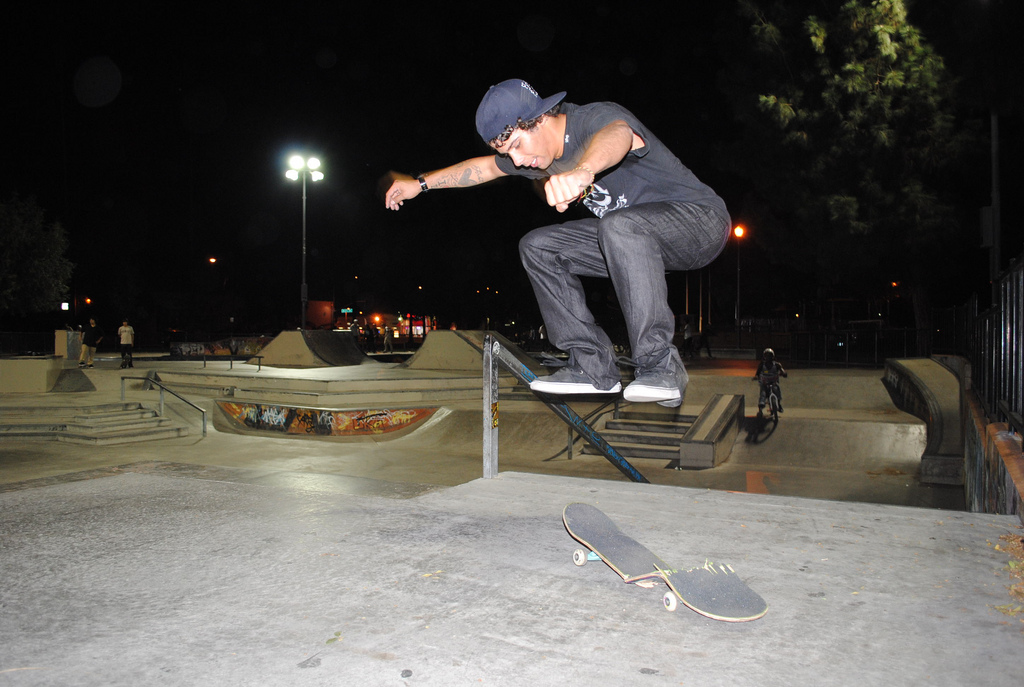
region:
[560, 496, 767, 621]
A broken wooden skateboard.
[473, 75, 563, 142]
A blue cap with white deisgn.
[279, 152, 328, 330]
A lampost with four white lights.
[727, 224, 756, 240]
A round and red light.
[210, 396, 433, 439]
Graffiti on the side of cement.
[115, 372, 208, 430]
A thin and black bar.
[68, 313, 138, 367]
Two guy standing in the background.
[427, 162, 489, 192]
Blank ink on the guys' arm.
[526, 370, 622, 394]
Black shoe with white base.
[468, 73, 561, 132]
Person wearing baseball hat on head.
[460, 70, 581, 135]
Person is wearing blue hat.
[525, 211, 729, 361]
Person wearing dark pants.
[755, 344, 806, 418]
Person in distance is sitting on bike.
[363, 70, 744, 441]
Person is doing a trick over skateboard.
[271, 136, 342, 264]
Large light illuminated in distance.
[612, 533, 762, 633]
Skateboard is broken in pieces.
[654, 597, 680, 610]
wheel attached to skateboard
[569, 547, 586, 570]
wheel attached to skateboard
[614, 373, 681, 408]
shoe on top of foot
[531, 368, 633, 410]
shoe on top of foot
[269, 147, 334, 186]
light fixture attached to pole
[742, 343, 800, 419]
person riding bike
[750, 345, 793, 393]
person on top of bike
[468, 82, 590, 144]
hat on top of head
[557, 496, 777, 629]
skateboard on top of cement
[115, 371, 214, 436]
rail near concrete steps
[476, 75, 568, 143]
Blue hat on a man in the air.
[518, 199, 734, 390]
Black pants on a man in the air.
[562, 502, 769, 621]
Black topped skateboard broken in half.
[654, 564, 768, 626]
Smaller broken half of a skateboard.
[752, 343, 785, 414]
Person on a bicycle at the top of a ramp.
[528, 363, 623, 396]
Man in the airs right black and white shoe.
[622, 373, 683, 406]
Man in the airs left black and white shoe.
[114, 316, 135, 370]
Boy standing in the background in a white shirt and black pants.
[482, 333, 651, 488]
Black and grey railing going down behind a man in the air.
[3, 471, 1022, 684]
Grey paved area a broken skateboard is on.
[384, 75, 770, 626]
the man above the broken skateboard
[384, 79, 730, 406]
the man is wearing a black watch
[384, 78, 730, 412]
the man has a tattoo on his forearm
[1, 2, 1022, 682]
the man at the skate park under the dark sky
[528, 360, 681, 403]
the shoes are black and white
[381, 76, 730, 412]
the man is wearing a black shirt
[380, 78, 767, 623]
the man is in mid air above the skateboard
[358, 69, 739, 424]
man jumping over skateboard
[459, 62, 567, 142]
man wearing ball cap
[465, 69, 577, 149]
mans cap is black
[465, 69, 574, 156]
mans cap is backward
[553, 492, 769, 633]
skateboard on top of concrete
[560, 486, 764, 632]
mans skateboard is broken